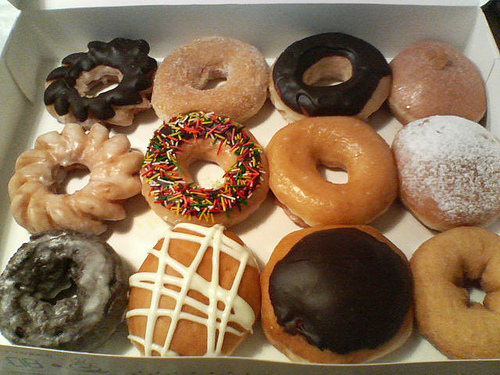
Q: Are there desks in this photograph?
A: No, there are no desks.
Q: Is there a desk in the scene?
A: No, there are no desks.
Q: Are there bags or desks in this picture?
A: No, there are no desks or bags.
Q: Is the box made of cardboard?
A: Yes, the box is made of cardboard.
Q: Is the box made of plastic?
A: No, the box is made of cardboard.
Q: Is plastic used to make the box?
A: No, the box is made of cardboard.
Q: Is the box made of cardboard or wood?
A: The box is made of cardboard.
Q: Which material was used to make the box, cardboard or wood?
A: The box is made of cardboard.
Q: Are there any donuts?
A: Yes, there are donuts.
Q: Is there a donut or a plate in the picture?
A: Yes, there are donuts.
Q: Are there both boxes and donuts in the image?
A: Yes, there are both donuts and a box.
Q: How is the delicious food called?
A: The food is donuts.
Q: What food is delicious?
A: The food is donuts.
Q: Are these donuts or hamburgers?
A: These are donuts.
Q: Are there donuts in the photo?
A: Yes, there is a donut.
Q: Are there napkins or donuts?
A: Yes, there is a donut.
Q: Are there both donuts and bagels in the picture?
A: No, there is a donut but no bagels.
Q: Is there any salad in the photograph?
A: No, there is no salad.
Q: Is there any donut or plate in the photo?
A: Yes, there is a donut.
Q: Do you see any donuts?
A: Yes, there is a donut.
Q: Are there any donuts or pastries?
A: Yes, there is a donut.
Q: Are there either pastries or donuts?
A: Yes, there is a donut.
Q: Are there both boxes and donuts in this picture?
A: Yes, there are both a donut and a box.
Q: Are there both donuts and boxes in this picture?
A: Yes, there are both a donut and a box.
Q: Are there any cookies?
A: No, there are no cookies.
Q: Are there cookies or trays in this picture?
A: No, there are no cookies or trays.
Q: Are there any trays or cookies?
A: No, there are no cookies or trays.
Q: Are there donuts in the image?
A: Yes, there is a donut.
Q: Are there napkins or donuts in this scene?
A: Yes, there is a donut.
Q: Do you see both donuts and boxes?
A: Yes, there are both a donut and a box.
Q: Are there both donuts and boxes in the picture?
A: Yes, there are both a donut and a box.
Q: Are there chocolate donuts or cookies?
A: Yes, there is a chocolate donut.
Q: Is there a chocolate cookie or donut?
A: Yes, there is a chocolate donut.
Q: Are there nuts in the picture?
A: No, there are no nuts.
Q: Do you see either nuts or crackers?
A: No, there are no nuts or crackers.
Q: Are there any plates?
A: Yes, there is a plate.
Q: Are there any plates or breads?
A: Yes, there is a plate.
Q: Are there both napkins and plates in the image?
A: No, there is a plate but no napkins.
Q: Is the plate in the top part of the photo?
A: Yes, the plate is in the top of the image.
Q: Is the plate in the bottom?
A: No, the plate is in the top of the image.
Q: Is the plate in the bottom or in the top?
A: The plate is in the top of the image.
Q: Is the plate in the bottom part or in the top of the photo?
A: The plate is in the top of the image.